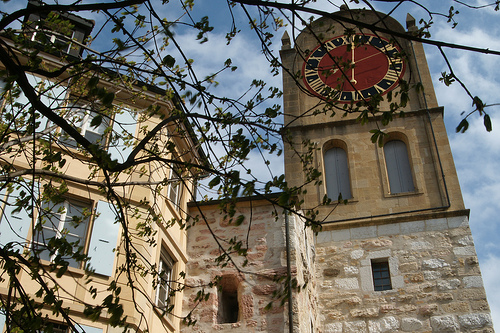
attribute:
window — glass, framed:
[371, 255, 393, 293]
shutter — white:
[82, 201, 173, 285]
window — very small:
[360, 247, 402, 301]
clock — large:
[296, 27, 408, 111]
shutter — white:
[0, 152, 145, 284]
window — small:
[215, 269, 243, 326]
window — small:
[370, 253, 395, 294]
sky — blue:
[1, 0, 498, 332]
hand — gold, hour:
[345, 37, 362, 98]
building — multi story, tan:
[215, 10, 461, 330]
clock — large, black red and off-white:
[298, 28, 416, 109]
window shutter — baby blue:
[86, 197, 121, 279]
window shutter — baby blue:
[4, 175, 48, 256]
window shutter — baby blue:
[103, 100, 138, 162]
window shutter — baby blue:
[32, 75, 68, 144]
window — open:
[360, 249, 403, 297]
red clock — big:
[293, 25, 413, 115]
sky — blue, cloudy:
[144, 9, 302, 97]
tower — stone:
[273, 6, 499, 331]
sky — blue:
[447, 12, 497, 98]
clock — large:
[288, 19, 414, 121]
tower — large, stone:
[282, 7, 482, 317]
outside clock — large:
[299, 26, 416, 108]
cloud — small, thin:
[433, 19, 498, 76]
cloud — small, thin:
[434, 62, 498, 116]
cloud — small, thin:
[449, 110, 498, 155]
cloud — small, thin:
[174, 30, 241, 68]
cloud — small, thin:
[192, 110, 283, 197]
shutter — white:
[2, 71, 72, 154]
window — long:
[319, 134, 356, 209]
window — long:
[379, 127, 419, 198]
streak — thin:
[89, 10, 277, 52]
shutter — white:
[1, 179, 41, 263]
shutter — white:
[85, 194, 123, 281]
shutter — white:
[106, 99, 139, 173]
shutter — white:
[3, 70, 64, 138]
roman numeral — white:
[351, 87, 365, 103]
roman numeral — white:
[382, 66, 402, 82]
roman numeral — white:
[322, 37, 338, 50]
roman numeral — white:
[381, 40, 396, 52]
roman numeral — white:
[302, 66, 321, 76]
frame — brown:
[362, 248, 399, 296]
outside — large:
[2, 7, 449, 331]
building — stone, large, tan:
[0, 11, 484, 330]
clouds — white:
[108, 2, 484, 211]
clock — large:
[294, 8, 437, 111]